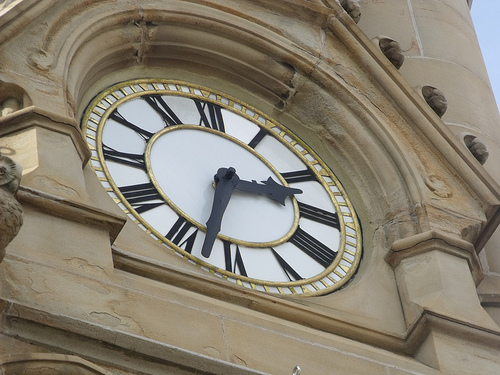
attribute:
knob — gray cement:
[413, 79, 453, 123]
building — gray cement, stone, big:
[4, 2, 497, 374]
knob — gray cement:
[464, 134, 486, 166]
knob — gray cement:
[418, 75, 449, 120]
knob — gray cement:
[370, 31, 405, 71]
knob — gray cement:
[339, 0, 362, 25]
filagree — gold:
[75, 68, 380, 307]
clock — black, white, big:
[77, 77, 367, 310]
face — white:
[101, 76, 365, 309]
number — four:
[215, 228, 245, 297]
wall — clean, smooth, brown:
[3, 2, 498, 372]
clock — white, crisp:
[88, 67, 396, 305]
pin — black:
[208, 159, 247, 191]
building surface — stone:
[6, 8, 494, 370]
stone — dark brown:
[375, 27, 412, 72]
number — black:
[136, 84, 188, 143]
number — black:
[159, 201, 215, 261]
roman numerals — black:
[291, 223, 339, 262]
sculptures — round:
[266, 45, 374, 114]